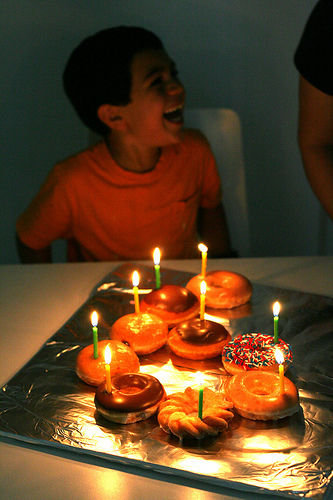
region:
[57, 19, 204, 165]
Smiling child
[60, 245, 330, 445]
Lit candles on doughnuts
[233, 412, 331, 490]
Aluminum foil under doughnuts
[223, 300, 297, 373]
Doughnut with red, white and blue sprinkles and a candle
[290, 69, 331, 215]
Part of someone's arm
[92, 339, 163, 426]
Chocolate frosted doughnut with a candle on top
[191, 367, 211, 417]
Lit green candle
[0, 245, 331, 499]
Doughnuts on a table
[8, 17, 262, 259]
Young boy sitting in a chair at the table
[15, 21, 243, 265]
Boy with orange t-shirt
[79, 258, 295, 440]
nine donuts in a table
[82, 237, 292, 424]
nine small burning candles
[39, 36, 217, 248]
kid laughing in front of donuts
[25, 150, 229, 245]
orange t-shirt of a kid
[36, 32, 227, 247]
kid with orange t-shirt laughing hard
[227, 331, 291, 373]
donut with chocolate chips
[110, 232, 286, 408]
five yellow candles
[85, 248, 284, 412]
four green candles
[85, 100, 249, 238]
back of a blue chair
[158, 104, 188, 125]
mouth open of a kid laughing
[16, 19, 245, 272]
a boy with a big smile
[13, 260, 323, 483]
donuts on a foil covered tray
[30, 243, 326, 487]
donuts that make the number 6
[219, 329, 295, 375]
the donut with rainbow sprinkles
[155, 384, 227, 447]
french cruler with a green candle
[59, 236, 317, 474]
9 donuts with lit candles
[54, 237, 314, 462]
donuts with birthday candles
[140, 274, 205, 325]
chocolate donut with a green candle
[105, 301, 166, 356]
jelly filled donut with a yellow candle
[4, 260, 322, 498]
a tray of birthday donuts on a table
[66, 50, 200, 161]
little boy smiling at man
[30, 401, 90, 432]
aluminum pan on table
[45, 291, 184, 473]
rounded square oven pan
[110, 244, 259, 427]
lit candles on donuts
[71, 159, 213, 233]
orange shirt with pocket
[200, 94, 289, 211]
white dining room chair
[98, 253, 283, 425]
the number 6 with donuts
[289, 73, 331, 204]
arm of someone with a black shirt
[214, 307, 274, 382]
sprinkle donut on pan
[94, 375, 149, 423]
chocolate glazed donut on pan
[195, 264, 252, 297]
a glazed donut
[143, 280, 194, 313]
a chocolate covered filled donut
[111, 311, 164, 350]
a jelly filled donut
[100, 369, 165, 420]
a chocolate covered cake donut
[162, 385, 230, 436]
a glazed crueller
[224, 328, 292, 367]
a red, white, and blue sprinkle covered donut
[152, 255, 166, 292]
a green candle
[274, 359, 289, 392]
a yellow candle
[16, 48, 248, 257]
a smiling child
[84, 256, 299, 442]
donuts in the shape of a 9